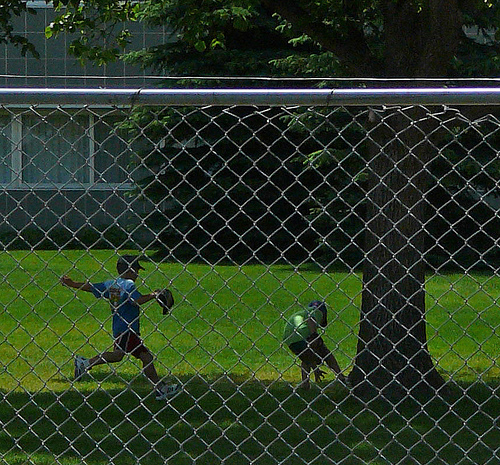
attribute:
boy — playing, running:
[61, 254, 177, 397]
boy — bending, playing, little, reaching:
[283, 299, 350, 389]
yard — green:
[0, 243, 489, 464]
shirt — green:
[285, 307, 323, 343]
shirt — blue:
[94, 278, 141, 332]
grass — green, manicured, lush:
[0, 249, 493, 464]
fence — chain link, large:
[1, 77, 498, 464]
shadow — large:
[0, 373, 499, 464]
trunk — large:
[350, 79, 444, 383]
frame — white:
[1, 180, 170, 194]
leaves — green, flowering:
[0, 1, 491, 80]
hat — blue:
[309, 300, 329, 324]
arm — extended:
[61, 274, 110, 294]